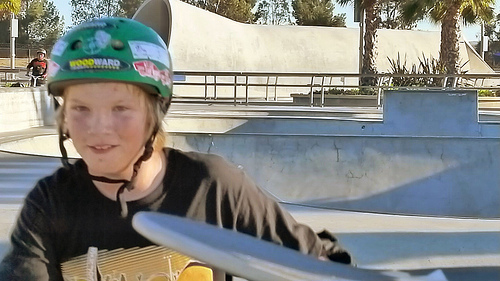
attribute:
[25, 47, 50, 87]
boy — background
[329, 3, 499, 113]
trees — large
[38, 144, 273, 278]
shirt — black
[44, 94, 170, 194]
straps — black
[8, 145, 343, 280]
shirt — black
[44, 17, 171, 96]
helmet — green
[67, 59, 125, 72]
colored logo — yellow